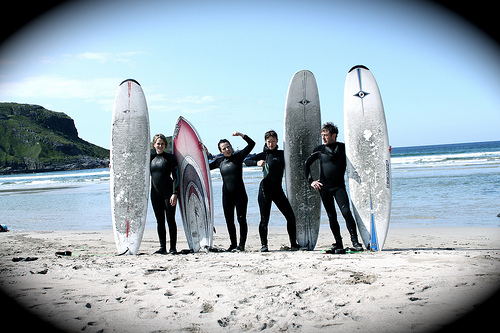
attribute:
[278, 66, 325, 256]
board — vertical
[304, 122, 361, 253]
person — group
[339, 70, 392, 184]
surfboard — white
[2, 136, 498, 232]
water — blue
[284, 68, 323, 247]
board — long, white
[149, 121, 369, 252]
people — group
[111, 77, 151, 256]
board — white long 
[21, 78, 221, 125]
clouds — white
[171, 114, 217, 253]
surfboard — white , red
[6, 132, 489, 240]
water — calm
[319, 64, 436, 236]
surfboard — white